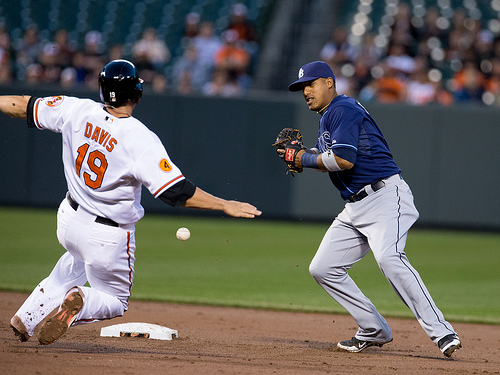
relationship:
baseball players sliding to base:
[0, 58, 265, 345] [104, 318, 189, 344]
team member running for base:
[21, 57, 173, 371] [104, 318, 189, 344]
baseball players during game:
[52, 56, 477, 341] [8, 4, 500, 356]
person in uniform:
[274, 59, 467, 357] [315, 114, 419, 369]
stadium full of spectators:
[4, 4, 488, 372] [27, 10, 489, 103]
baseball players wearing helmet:
[0, 58, 265, 345] [96, 59, 144, 109]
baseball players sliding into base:
[0, 58, 265, 345] [104, 318, 189, 344]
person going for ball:
[274, 59, 467, 357] [173, 224, 191, 242]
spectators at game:
[27, 10, 489, 103] [8, 4, 500, 356]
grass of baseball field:
[3, 209, 466, 310] [14, 208, 472, 374]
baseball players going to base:
[0, 58, 265, 345] [104, 318, 189, 344]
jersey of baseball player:
[50, 94, 130, 321] [46, 93, 133, 336]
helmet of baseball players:
[96, 64, 132, 89] [0, 58, 265, 345]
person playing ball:
[282, 55, 447, 363] [173, 224, 191, 242]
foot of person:
[324, 318, 396, 357] [282, 55, 447, 363]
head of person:
[291, 55, 336, 113] [282, 55, 447, 363]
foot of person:
[425, 324, 467, 359] [282, 55, 447, 363]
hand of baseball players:
[226, 198, 272, 224] [0, 58, 265, 345]